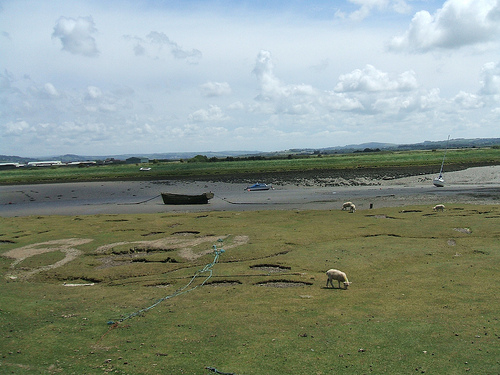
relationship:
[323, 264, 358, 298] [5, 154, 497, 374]
sheep on grass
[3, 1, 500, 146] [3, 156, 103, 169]
sky above buildings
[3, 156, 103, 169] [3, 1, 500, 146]
buildings under sky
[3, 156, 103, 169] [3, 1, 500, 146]
buildings below sky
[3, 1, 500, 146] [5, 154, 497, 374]
sky above grass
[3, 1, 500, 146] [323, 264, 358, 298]
sky above sheep